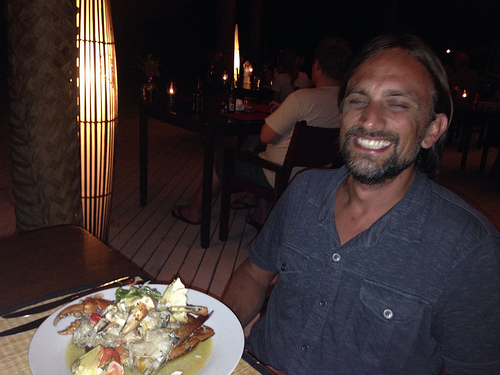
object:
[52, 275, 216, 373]
foods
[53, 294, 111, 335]
crab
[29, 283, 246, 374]
plate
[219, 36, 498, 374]
man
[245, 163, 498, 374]
shirt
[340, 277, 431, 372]
pocket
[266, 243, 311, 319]
pocket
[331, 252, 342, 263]
button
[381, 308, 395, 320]
button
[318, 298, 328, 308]
button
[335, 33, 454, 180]
hair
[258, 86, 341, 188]
shirt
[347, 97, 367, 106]
eye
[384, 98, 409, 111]
eye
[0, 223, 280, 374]
table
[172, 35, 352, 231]
man